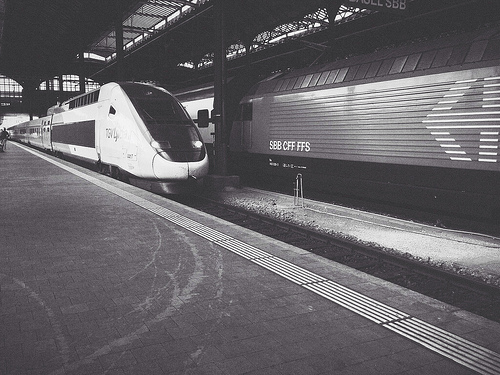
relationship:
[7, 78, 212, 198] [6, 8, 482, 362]
train in a terminal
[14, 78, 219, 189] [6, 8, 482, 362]
train in a terminal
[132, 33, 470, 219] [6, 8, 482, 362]
train in a terminal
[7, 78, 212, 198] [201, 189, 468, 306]
train on a track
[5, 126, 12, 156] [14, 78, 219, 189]
people waiting for a train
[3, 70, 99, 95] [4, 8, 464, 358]
windows in a train station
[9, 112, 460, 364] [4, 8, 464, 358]
floor at a train station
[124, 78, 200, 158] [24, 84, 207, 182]
windshield on a train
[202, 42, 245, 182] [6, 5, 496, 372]
support beam in a train station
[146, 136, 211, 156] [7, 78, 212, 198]
headlights on a train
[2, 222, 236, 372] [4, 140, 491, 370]
stains on floor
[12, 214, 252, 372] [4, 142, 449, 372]
stains on floor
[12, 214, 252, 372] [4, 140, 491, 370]
stains on floor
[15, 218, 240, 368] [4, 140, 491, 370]
stains on floor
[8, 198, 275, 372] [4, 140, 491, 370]
stains on floor